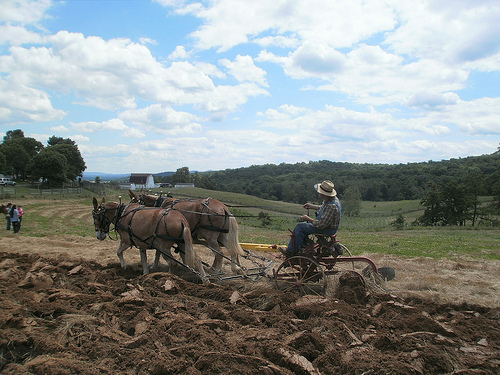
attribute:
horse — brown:
[89, 196, 208, 285]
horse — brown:
[124, 191, 247, 271]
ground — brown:
[2, 235, 497, 374]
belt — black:
[314, 223, 340, 233]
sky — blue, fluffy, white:
[0, 0, 500, 174]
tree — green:
[25, 148, 67, 180]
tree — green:
[54, 141, 84, 172]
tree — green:
[0, 146, 31, 175]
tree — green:
[429, 181, 479, 226]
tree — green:
[343, 184, 362, 215]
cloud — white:
[52, 32, 120, 71]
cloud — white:
[170, 62, 213, 95]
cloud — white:
[192, 0, 290, 54]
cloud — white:
[354, 42, 408, 81]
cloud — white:
[416, 87, 464, 110]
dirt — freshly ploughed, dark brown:
[0, 252, 497, 372]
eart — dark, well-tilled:
[67, 261, 402, 373]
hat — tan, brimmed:
[310, 179, 345, 200]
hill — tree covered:
[176, 147, 499, 210]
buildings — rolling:
[127, 167, 198, 192]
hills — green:
[0, 142, 498, 260]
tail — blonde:
[180, 223, 197, 273]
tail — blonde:
[223, 213, 245, 259]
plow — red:
[216, 230, 387, 309]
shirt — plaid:
[302, 179, 404, 270]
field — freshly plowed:
[6, 250, 499, 373]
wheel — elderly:
[273, 253, 327, 306]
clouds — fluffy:
[42, 40, 467, 117]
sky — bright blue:
[1, 5, 491, 160]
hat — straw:
[315, 178, 338, 197]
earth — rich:
[3, 244, 497, 366]